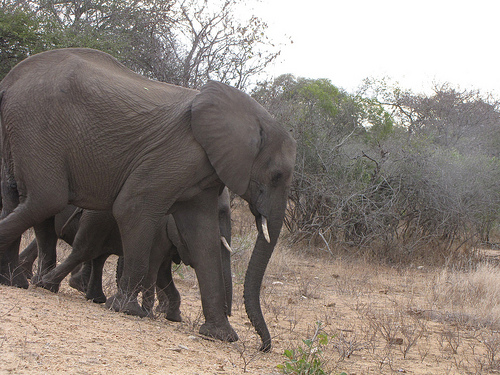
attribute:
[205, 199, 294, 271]
tusk — small, white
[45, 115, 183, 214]
skin — wrinkled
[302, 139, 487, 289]
wood — dark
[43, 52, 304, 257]
elephant — look